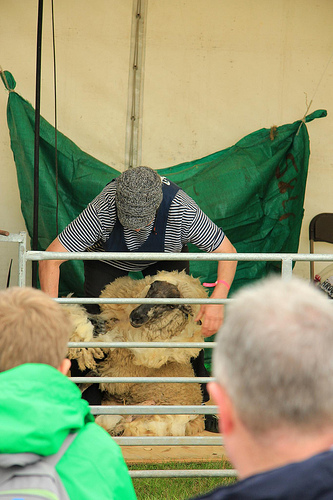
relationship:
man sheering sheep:
[44, 167, 237, 266] [98, 269, 203, 424]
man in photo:
[44, 167, 237, 266] [1, 2, 329, 493]